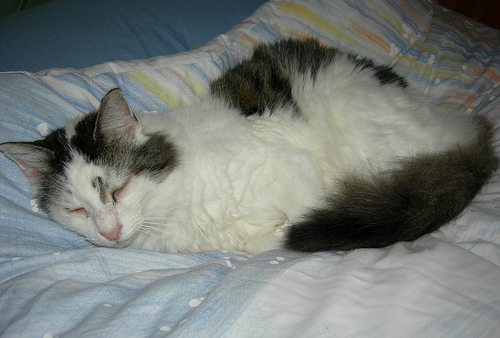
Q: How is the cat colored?
A: Black and white.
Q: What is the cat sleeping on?
A: Bed.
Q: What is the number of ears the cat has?
A: Two.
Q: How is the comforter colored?
A: Light blue.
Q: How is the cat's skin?
A: Fluffy.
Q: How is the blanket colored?
A: Blue and white.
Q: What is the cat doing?
A: Taking a nap.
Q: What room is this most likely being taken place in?
A: Bedroom.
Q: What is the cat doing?
A: Sleeping.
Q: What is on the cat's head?
A: White stripes.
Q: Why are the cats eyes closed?
A: It's sleeping.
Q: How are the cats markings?
A: Black and white.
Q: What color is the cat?
A: Black and white.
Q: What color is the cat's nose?
A: Pink.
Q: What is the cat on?
A: Blankets.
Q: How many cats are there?
A: One.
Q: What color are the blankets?
A: White, blue, yellow, and orange.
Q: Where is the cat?
A: On the blankets.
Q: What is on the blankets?
A: The cat.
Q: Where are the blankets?
A: Under the cat.